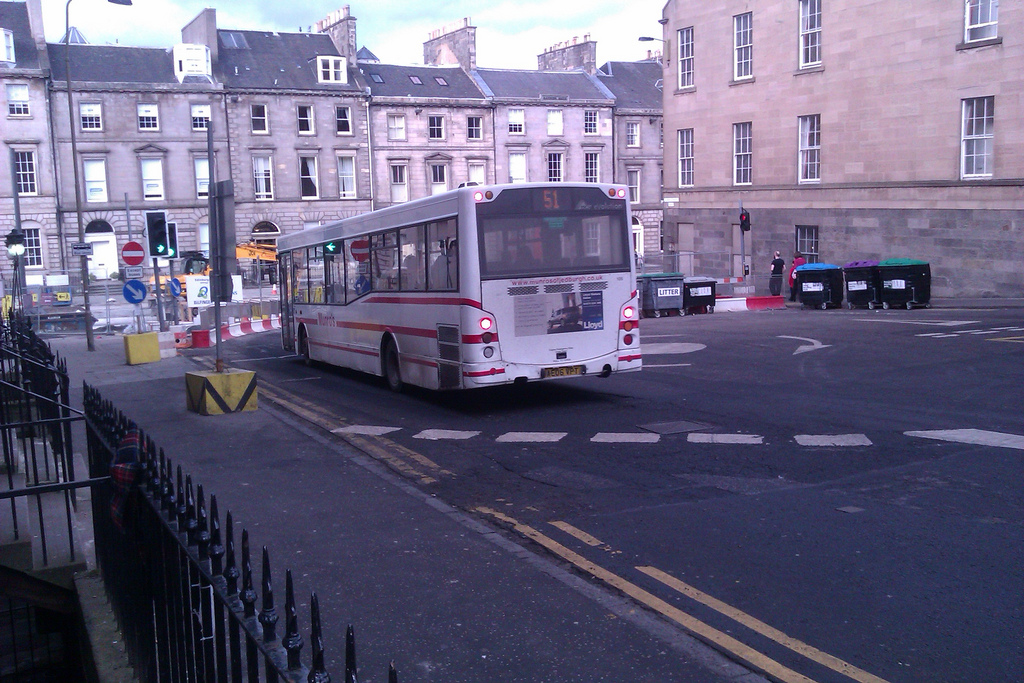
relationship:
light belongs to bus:
[477, 317, 494, 332] [283, 175, 612, 448]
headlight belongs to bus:
[566, 299, 715, 404] [280, 188, 715, 404]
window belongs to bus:
[408, 207, 675, 347] [408, 207, 675, 347]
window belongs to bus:
[391, 220, 607, 369] [391, 220, 607, 369]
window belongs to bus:
[318, 223, 660, 363] [318, 223, 660, 363]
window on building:
[3, 68, 165, 206] [0, 0, 663, 308]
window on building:
[56, 44, 244, 209] [0, 0, 663, 308]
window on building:
[707, 50, 1011, 250] [707, 50, 1011, 250]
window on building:
[874, 68, 1020, 236] [874, 68, 1020, 236]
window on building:
[803, 11, 1009, 198] [803, 11, 1009, 198]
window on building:
[702, 14, 996, 262] [702, 14, 996, 262]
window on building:
[656, 59, 849, 224] [656, 59, 849, 224]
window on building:
[628, 113, 844, 232] [628, 113, 844, 232]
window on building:
[670, 125, 698, 188] [642, 31, 833, 178]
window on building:
[698, 6, 926, 165] [698, 6, 926, 165]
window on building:
[493, 77, 708, 229] [493, 77, 708, 229]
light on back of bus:
[457, 286, 524, 391] [457, 140, 729, 391]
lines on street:
[397, 456, 702, 609] [397, 289, 1014, 609]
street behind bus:
[0, 297, 1022, 681] [283, 205, 989, 591]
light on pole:
[113, 197, 227, 302] [113, 197, 227, 302]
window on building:
[726, 119, 755, 187] [601, 84, 1017, 263]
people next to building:
[744, 224, 847, 308] [648, 10, 1020, 315]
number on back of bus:
[509, 169, 592, 237] [263, 174, 650, 417]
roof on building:
[340, 37, 518, 124] [2, 5, 657, 341]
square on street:
[318, 404, 399, 442] [118, 269, 1017, 676]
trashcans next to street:
[777, 264, 987, 391] [777, 264, 987, 391]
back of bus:
[451, 167, 668, 438] [306, 201, 794, 487]